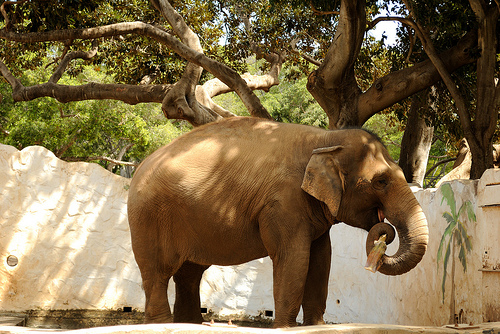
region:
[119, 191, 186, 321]
Leg of an elephant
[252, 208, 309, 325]
Leg of an elephant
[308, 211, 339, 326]
Leg of an elephant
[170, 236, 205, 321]
Leg of an elephant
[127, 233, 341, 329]
Legs of an elephant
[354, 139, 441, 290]
Trunk of an elephant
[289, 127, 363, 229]
Ear of an elephant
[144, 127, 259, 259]
Stomach of an elephant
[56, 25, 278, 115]
Branch of a tree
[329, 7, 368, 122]
Branch of a tree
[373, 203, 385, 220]
The elephant's mouth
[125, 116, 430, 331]
An elephant feeding with its trunk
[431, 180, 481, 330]
A painting of a palm tree on the enclosure wall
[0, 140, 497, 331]
A wall around the elephant's enclosure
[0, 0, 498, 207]
Surrounding trees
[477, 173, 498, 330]
Metal bars on the enclosure, maybe for its gate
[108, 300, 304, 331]
Holes in the wall for draining the enclosure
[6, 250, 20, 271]
A light mounted in the enclosure wall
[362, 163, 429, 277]
The elephant's coiled trunk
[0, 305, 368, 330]
Floor of the enclosure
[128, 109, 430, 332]
brown elephant eating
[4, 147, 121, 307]
rock barrier around elephant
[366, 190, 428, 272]
trunk of an elephant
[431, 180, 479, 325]
drawing of a palm tree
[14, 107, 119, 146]
tree with green leaves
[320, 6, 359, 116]
trunk of a tree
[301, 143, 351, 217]
ear of an elephant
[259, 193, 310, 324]
front leg of an elephant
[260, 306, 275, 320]
drain hole in rock wall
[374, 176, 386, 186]
ELEPHANT HAS A BROWN EYE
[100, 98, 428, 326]
large gray elephant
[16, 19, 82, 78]
green leaves on gray and brown trees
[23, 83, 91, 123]
green leaves on gray and brown trees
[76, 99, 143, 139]
green leaves on gray and brown trees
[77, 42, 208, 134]
green leaves on gray and brown trees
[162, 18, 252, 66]
green leaves on gray and brown trees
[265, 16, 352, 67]
green leaves on gray and brown trees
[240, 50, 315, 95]
green leaves on gray and brown trees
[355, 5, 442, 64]
green leaves on gray and brown trees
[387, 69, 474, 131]
green leaves on gray and brown trees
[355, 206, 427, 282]
An elephant trunk eating a branch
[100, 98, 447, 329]
An elephant eating a branch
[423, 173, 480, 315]
a painting of a palm tree on a wall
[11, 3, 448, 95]
Large branches of a tree in the background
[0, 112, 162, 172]
Trees on the further horizon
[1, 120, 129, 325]
Stucca wall fencing in the elephant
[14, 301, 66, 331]
grass on the ground behind the elephant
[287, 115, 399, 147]
dark brown hair on the elephant's head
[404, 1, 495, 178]
thick portion of trees outside the elephant's pen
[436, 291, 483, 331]
Metal fixture inside the elephant's pen